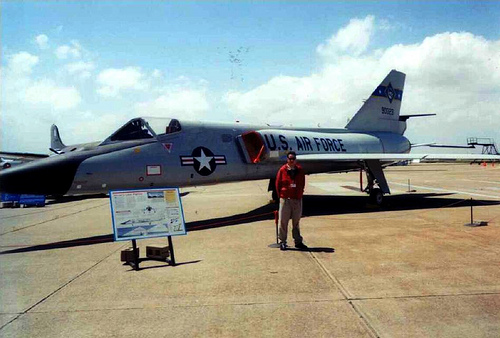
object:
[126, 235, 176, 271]
stand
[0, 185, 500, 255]
shadow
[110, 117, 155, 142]
windshield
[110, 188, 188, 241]
sign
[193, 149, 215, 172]
whitestar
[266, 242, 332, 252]
shadow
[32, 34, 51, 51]
clouds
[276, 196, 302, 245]
pants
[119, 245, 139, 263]
cinder block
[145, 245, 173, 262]
cinder block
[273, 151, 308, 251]
man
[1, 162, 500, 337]
ground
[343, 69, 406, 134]
tail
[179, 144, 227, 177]
army sign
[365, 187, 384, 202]
tire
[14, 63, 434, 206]
plane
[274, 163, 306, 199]
shirt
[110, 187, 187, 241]
board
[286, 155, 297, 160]
sunglasses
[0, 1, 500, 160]
sky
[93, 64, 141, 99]
clouds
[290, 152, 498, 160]
wing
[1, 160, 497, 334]
runway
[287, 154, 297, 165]
face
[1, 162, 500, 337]
floor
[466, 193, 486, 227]
object